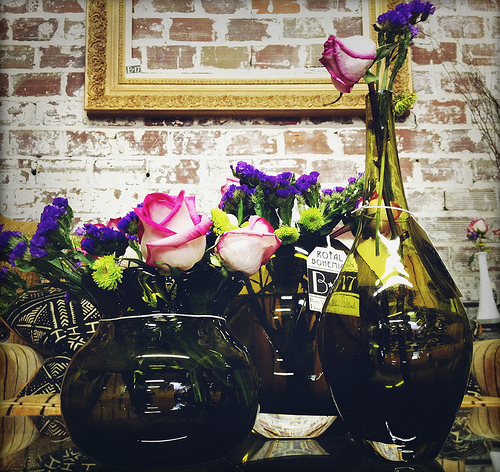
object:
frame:
[81, 0, 410, 117]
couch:
[462, 339, 500, 397]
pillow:
[0, 288, 103, 399]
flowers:
[318, 0, 435, 92]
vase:
[57, 311, 256, 470]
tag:
[306, 245, 359, 319]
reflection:
[135, 352, 191, 361]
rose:
[132, 189, 213, 271]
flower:
[231, 160, 265, 184]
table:
[0, 404, 497, 472]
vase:
[315, 91, 474, 467]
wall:
[2, 0, 498, 304]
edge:
[83, 1, 88, 110]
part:
[376, 210, 381, 218]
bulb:
[252, 412, 338, 440]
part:
[97, 262, 106, 276]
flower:
[90, 254, 124, 291]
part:
[398, 43, 406, 58]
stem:
[374, 45, 391, 260]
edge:
[117, 265, 123, 285]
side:
[315, 281, 334, 403]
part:
[0, 0, 32, 17]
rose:
[318, 34, 377, 93]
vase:
[475, 251, 500, 321]